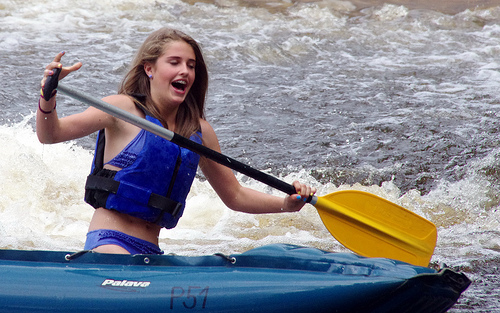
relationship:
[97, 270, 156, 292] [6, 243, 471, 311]
writing on boat